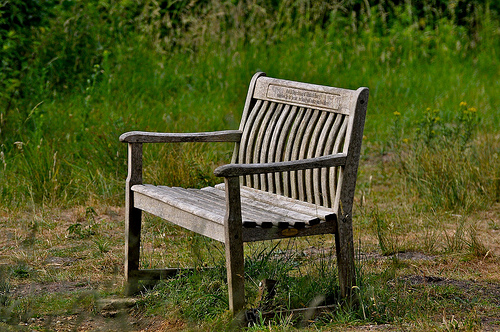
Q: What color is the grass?
A: Green.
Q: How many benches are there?
A: One.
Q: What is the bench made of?
A: Wood.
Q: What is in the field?
A: Tall grass.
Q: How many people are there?
A: None.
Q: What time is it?
A: Afternoon.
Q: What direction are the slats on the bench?
A: Vertical.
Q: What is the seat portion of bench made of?
A: Wood.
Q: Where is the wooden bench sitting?
A: In weeds.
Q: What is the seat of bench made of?
A: Wood.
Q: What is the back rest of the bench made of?
A: Wood.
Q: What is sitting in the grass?
A: A bench.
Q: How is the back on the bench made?
A: Curved.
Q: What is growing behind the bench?
A: Tall grass.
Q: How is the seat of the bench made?
A: It has a dip.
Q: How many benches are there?
A: One.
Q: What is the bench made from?
A: Wood.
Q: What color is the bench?
A: Brown.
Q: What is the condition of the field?
A: It is slightly overrun.